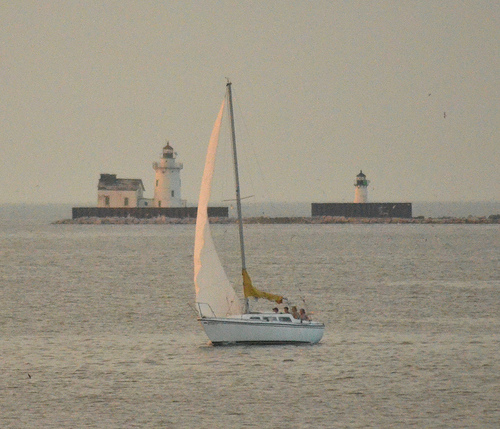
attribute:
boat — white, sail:
[164, 255, 364, 380]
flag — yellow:
[236, 244, 292, 308]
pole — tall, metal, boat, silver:
[222, 73, 257, 322]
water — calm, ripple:
[73, 239, 139, 305]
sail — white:
[168, 80, 245, 314]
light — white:
[144, 129, 196, 213]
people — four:
[272, 304, 307, 318]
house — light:
[152, 150, 187, 194]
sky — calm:
[66, 47, 148, 131]